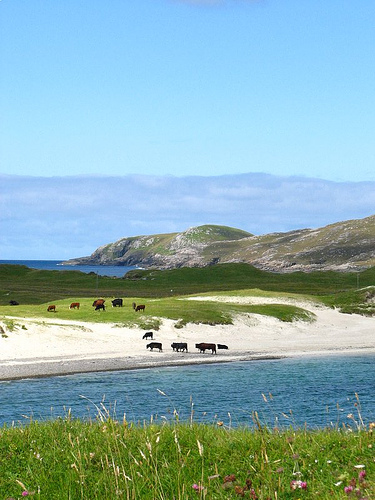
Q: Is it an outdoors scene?
A: Yes, it is outdoors.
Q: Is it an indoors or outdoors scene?
A: It is outdoors.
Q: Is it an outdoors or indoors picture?
A: It is outdoors.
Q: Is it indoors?
A: No, it is outdoors.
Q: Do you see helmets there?
A: No, there are no helmets.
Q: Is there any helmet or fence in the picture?
A: No, there are no helmets or fences.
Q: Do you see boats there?
A: No, there are no boats.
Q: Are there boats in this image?
A: No, there are no boats.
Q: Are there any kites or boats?
A: No, there are no boats or kites.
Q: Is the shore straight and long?
A: Yes, the shore is straight and long.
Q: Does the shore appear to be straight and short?
A: No, the shore is straight but long.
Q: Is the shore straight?
A: Yes, the shore is straight.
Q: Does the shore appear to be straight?
A: Yes, the shore is straight.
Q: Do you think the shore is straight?
A: Yes, the shore is straight.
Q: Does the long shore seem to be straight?
A: Yes, the shore is straight.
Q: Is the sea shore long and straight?
A: Yes, the sea shore is long and straight.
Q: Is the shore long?
A: Yes, the shore is long.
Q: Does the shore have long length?
A: Yes, the shore is long.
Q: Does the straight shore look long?
A: Yes, the sea shore is long.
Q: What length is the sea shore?
A: The sea shore is long.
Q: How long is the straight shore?
A: The shore is long.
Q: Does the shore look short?
A: No, the shore is long.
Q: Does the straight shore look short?
A: No, the shore is long.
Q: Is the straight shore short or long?
A: The sea shore is long.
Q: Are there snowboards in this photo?
A: No, there are no snowboards.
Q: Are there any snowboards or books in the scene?
A: No, there are no snowboards or books.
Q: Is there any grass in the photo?
A: Yes, there is grass.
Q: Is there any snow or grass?
A: Yes, there is grass.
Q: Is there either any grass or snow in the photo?
A: Yes, there is grass.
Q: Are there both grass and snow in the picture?
A: No, there is grass but no snow.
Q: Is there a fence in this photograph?
A: No, there are no fences.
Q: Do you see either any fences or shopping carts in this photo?
A: No, there are no fences or shopping carts.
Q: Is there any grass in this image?
A: Yes, there is grass.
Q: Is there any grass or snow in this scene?
A: Yes, there is grass.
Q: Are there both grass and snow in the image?
A: No, there is grass but no snow.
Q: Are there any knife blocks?
A: No, there are no knife blocks.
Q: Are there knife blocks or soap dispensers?
A: No, there are no knife blocks or soap dispensers.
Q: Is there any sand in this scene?
A: Yes, there is sand.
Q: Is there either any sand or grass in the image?
A: Yes, there is sand.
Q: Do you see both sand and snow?
A: No, there is sand but no snow.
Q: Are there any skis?
A: No, there are no skis.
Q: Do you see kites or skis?
A: No, there are no skis or kites.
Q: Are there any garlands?
A: No, there are no garlands.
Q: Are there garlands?
A: No, there are no garlands.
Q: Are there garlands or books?
A: No, there are no garlands or books.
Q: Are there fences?
A: No, there are no fences.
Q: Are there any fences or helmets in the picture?
A: No, there are no fences or helmets.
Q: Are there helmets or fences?
A: No, there are no fences or helmets.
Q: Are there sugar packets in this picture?
A: No, there are no sugar packets.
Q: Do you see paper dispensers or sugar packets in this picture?
A: No, there are no sugar packets or paper dispensers.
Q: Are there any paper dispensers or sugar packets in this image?
A: No, there are no sugar packets or paper dispensers.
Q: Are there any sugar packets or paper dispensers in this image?
A: No, there are no sugar packets or paper dispensers.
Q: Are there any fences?
A: No, there are no fences.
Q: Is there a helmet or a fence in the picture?
A: No, there are no fences or helmets.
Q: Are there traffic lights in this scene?
A: No, there are no traffic lights.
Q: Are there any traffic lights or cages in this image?
A: No, there are no traffic lights or cages.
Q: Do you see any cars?
A: No, there are no cars.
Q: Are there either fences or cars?
A: No, there are no cars or fences.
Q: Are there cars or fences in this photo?
A: No, there are no cars or fences.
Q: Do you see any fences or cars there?
A: No, there are no cars or fences.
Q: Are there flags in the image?
A: No, there are no flags.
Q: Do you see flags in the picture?
A: No, there are no flags.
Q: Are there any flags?
A: No, there are no flags.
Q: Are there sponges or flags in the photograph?
A: No, there are no flags or sponges.